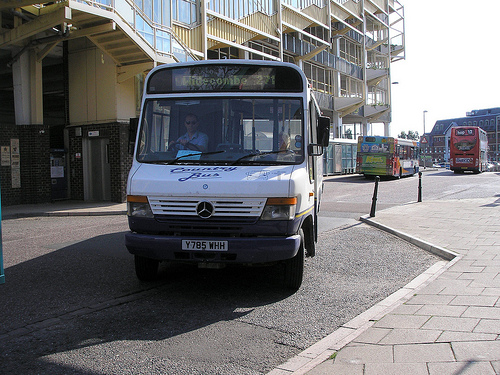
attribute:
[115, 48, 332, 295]
bus — multi-colored, red, white, colorful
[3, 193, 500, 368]
street — stone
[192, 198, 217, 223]
sign — mercedes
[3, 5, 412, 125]
building — large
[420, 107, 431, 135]
post — metal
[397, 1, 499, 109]
sky — white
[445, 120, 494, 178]
bus — double decker, red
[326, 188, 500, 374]
sidewalk — tiled, gray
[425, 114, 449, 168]
building — red